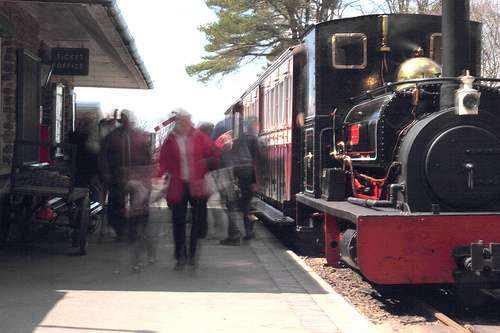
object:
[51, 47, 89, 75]
sign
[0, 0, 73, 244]
ticket office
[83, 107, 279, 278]
people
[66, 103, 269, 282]
focus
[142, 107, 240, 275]
lady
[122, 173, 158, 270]
child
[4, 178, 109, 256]
bench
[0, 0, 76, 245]
wall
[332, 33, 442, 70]
front windows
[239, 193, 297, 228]
loading dock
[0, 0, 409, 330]
train station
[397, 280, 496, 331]
tracks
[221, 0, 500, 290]
red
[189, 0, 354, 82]
tree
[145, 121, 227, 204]
red coat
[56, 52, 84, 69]
ticket office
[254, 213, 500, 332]
gravel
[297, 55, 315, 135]
passengers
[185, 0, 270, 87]
leaves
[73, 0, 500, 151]
sky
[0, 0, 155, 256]
building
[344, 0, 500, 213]
steam egine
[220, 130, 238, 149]
hand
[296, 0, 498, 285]
train engine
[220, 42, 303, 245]
passager car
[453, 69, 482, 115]
lantern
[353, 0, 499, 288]
front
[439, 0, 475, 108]
smoke stack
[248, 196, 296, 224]
boarding platform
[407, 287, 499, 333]
set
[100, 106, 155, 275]
pedestrian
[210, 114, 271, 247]
pedestrian